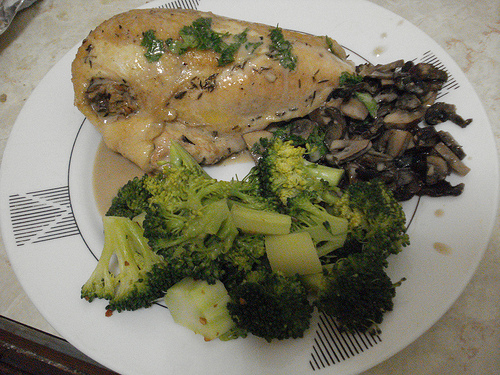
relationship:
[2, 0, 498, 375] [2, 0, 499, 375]
plate on table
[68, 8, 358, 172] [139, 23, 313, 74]
chicken has vegetables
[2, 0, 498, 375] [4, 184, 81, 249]
plate has stripes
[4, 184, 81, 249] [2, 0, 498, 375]
stripes on plate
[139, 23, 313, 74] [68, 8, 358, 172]
herbs on chicken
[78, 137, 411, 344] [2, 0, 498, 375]
broccoli on plate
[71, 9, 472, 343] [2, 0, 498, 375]
food on plate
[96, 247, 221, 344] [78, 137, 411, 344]
pepper flakes on broccoli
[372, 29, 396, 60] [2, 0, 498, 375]
oil on side of plate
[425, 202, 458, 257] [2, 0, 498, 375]
oil on side of plate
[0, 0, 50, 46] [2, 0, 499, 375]
napkin on table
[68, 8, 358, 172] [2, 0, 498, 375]
chicken on plate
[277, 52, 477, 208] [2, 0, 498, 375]
mushrooms on plate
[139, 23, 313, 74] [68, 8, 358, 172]
vegetables on chicken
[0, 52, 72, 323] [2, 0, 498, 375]
edge of plate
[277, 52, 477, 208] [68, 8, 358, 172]
mushrooms next to chicken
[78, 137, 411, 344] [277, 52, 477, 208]
broccoli next to mushrooms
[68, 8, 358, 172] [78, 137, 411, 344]
chicken next to broccoli